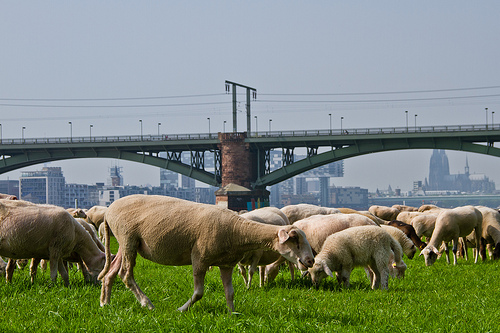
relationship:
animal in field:
[307, 224, 415, 289] [220, 265, 490, 330]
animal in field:
[95, 187, 316, 312] [220, 265, 490, 330]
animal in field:
[0, 204, 117, 283] [220, 265, 490, 330]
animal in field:
[418, 205, 486, 265] [220, 265, 490, 330]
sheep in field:
[400, 210, 437, 240] [220, 265, 490, 330]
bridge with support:
[1, 79, 498, 211] [291, 130, 499, 156]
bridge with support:
[1, 79, 498, 211] [9, 142, 205, 174]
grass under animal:
[1, 235, 498, 332] [103, 187, 315, 311]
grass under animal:
[1, 235, 498, 332] [307, 222, 393, 293]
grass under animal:
[1, 235, 498, 332] [415, 205, 482, 265]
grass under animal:
[1, 235, 498, 332] [263, 212, 378, 287]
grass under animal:
[1, 235, 498, 332] [0, 198, 115, 284]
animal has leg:
[95, 187, 316, 312] [107, 230, 155, 308]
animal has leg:
[95, 187, 316, 312] [94, 233, 126, 307]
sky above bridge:
[246, 8, 426, 74] [4, 80, 497, 195]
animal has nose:
[103, 187, 315, 311] [299, 256, 314, 268]